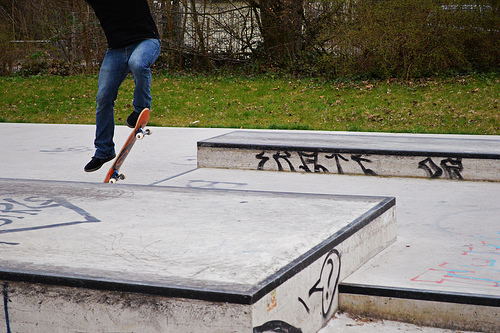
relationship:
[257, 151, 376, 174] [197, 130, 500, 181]
graffiti drawn on platform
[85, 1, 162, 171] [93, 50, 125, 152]
person has leg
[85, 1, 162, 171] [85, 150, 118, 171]
person wearing shoe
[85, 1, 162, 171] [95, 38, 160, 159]
person wearing jeans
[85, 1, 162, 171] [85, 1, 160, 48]
person wearing shirt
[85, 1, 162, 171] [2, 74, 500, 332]
person above ground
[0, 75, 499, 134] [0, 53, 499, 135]
grass growing in field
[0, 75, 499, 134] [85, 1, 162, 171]
grass behind person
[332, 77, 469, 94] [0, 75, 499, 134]
leaves on top of grass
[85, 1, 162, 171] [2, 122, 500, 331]
person in skatepark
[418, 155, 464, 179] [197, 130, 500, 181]
graffiti painted on platform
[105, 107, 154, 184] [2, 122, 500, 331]
skateboard inside skatepark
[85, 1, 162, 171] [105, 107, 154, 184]
person riding skateboard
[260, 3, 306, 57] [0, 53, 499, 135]
tree behind field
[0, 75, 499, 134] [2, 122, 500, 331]
grass next to skatepark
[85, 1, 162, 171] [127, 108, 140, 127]
person wearing shoe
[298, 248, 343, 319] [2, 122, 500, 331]
graffiti inside skatepark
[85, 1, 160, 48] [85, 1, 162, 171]
shirt worn by person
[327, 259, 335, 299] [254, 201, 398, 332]
question mark painted on cement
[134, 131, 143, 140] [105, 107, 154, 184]
wheel attached to skateboard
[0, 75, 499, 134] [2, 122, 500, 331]
grass behind skatepark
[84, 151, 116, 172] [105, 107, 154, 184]
foot above skateboard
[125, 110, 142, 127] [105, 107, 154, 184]
foot above skateboard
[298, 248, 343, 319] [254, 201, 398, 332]
graffiti painted on cement